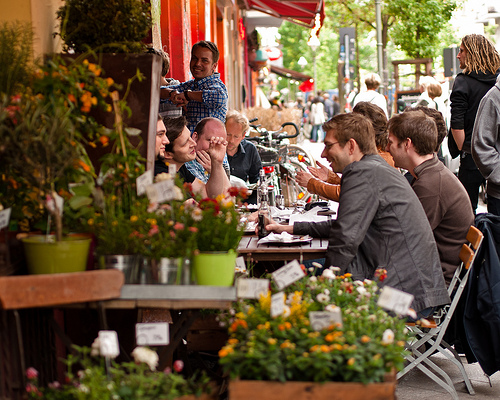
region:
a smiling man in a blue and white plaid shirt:
[158, 39, 230, 180]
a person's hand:
[201, 133, 230, 162]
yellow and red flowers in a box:
[219, 261, 414, 398]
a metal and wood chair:
[397, 225, 480, 398]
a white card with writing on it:
[133, 323, 170, 346]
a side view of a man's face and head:
[318, 111, 374, 174]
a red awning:
[262, 60, 315, 92]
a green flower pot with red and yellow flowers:
[193, 195, 243, 286]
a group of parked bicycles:
[247, 122, 314, 205]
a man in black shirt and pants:
[448, 31, 498, 211]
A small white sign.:
[238, 280, 268, 295]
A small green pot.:
[191, 253, 233, 292]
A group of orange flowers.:
[273, 328, 339, 358]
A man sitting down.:
[258, 114, 451, 315]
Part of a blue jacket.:
[474, 300, 494, 334]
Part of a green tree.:
[403, 15, 437, 53]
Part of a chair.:
[457, 225, 483, 271]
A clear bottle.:
[256, 186, 268, 238]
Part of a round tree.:
[57, 3, 152, 49]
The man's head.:
[321, 111, 381, 173]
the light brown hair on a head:
[321, 111, 374, 155]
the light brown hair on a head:
[353, 100, 388, 150]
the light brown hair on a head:
[386, 110, 435, 153]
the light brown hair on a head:
[404, 103, 447, 138]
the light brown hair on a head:
[462, 32, 496, 75]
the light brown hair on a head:
[192, 37, 221, 62]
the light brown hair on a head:
[229, 112, 251, 129]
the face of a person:
[179, 128, 197, 161]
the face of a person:
[227, 125, 238, 151]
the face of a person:
[320, 136, 340, 169]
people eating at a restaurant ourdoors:
[169, 73, 471, 265]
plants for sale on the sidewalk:
[4, 58, 405, 393]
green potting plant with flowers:
[196, 196, 238, 283]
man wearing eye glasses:
[315, 115, 373, 176]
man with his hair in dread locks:
[443, 27, 497, 84]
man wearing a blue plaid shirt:
[168, 42, 229, 121]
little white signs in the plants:
[141, 176, 185, 211]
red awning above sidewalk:
[231, 0, 336, 33]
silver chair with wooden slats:
[395, 213, 485, 380]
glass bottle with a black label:
[255, 183, 282, 238]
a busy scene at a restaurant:
[47, 23, 497, 327]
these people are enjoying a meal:
[139, 25, 436, 263]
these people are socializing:
[132, 109, 433, 209]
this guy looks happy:
[164, 38, 231, 113]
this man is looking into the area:
[435, 29, 496, 156]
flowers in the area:
[22, 51, 185, 258]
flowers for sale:
[209, 295, 400, 370]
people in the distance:
[280, 59, 340, 121]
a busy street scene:
[264, 54, 499, 255]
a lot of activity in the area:
[149, 28, 485, 268]